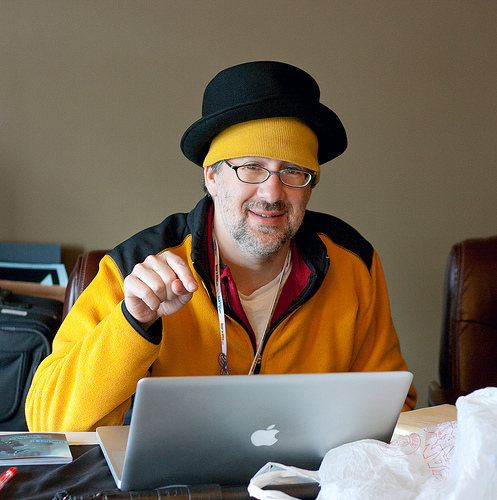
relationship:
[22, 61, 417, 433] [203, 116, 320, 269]
man has head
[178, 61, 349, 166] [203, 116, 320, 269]
hat on head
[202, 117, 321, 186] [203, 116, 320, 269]
hat on head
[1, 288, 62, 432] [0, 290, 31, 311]
bag has handle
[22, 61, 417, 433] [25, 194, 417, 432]
man wearing sweater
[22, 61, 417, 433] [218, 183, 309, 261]
man has beard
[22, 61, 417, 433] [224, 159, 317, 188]
man wearing eyeglasses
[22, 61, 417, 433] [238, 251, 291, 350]
man wearing under shirt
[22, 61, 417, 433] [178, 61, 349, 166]
man wearing hat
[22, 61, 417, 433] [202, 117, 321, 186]
man wearing hat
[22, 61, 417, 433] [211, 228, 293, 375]
man has lanyard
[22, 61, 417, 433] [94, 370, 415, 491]
man pointing at laptop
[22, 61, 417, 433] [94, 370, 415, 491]
man has laptop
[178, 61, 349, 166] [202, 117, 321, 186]
hat on top of hat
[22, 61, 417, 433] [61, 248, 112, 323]
man using chair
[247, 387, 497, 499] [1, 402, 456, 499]
grocery bag sitting on table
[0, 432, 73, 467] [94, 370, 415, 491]
book next to laptop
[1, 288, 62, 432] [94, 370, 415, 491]
bag for laptop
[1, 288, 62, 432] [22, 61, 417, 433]
bag beside man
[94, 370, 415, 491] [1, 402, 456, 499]
laptop on table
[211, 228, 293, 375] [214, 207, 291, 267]
lanyard on neck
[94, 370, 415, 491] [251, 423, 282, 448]
laptop has apple icon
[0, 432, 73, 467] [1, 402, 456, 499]
book on top of table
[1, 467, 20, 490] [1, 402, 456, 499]
pen on table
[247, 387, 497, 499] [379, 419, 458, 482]
grocery bag has writing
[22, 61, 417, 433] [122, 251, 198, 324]
man has hand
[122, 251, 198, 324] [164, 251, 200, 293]
hand has finger